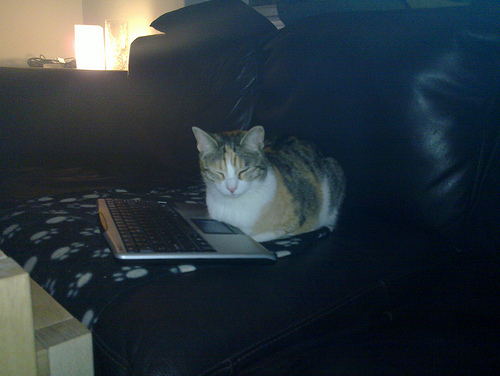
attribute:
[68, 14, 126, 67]
light shade — bright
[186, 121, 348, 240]
cat — sleeping, white, brown, black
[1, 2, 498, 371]
couch — black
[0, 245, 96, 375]
table — coffee, tan, wood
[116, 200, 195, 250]
keyboard — grey, wireless, black, silver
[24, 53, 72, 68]
cords — black